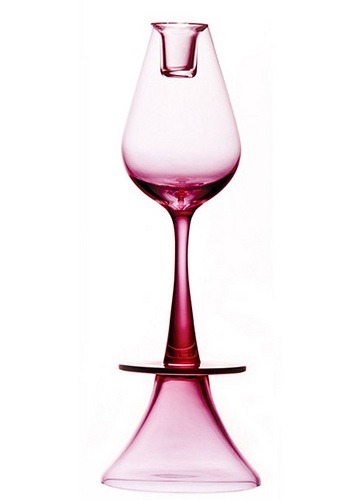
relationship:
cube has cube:
[150, 21, 207, 79] [164, 44, 232, 88]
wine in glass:
[144, 185, 248, 214] [104, 13, 351, 340]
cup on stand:
[142, 107, 268, 305] [131, 340, 297, 410]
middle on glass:
[163, 216, 203, 367] [104, 13, 351, 340]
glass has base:
[104, 13, 351, 340] [105, 377, 246, 496]